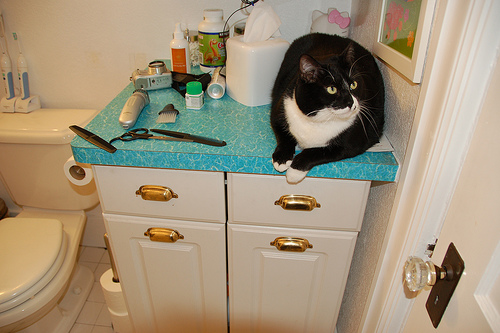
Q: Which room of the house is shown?
A: It is a bathroom.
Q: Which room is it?
A: It is a bathroom.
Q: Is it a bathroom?
A: Yes, it is a bathroom.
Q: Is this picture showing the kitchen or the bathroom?
A: It is showing the bathroom.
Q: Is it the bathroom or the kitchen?
A: It is the bathroom.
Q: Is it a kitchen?
A: No, it is a bathroom.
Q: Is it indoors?
A: Yes, it is indoors.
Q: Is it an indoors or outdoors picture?
A: It is indoors.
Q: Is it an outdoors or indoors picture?
A: It is indoors.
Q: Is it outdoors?
A: No, it is indoors.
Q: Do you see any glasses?
A: No, there are no glasses.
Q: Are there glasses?
A: No, there are no glasses.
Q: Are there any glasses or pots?
A: No, there are no glasses or pots.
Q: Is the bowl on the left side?
A: Yes, the bowl is on the left of the image.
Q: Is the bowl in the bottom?
A: Yes, the bowl is in the bottom of the image.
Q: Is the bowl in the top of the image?
A: No, the bowl is in the bottom of the image.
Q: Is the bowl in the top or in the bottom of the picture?
A: The bowl is in the bottom of the image.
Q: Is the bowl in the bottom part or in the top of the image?
A: The bowl is in the bottom of the image.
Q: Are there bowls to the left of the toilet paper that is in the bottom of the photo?
A: Yes, there is a bowl to the left of the toilet paper.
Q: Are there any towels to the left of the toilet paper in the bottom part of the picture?
A: No, there is a bowl to the left of the toilet paper.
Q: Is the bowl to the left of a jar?
A: No, the bowl is to the left of a toilet paper.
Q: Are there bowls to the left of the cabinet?
A: Yes, there is a bowl to the left of the cabinet.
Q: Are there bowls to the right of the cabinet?
A: No, the bowl is to the left of the cabinet.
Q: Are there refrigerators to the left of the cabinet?
A: No, there is a bowl to the left of the cabinet.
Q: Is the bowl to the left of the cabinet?
A: Yes, the bowl is to the left of the cabinet.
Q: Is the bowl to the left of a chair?
A: No, the bowl is to the left of the cabinet.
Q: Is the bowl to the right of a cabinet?
A: No, the bowl is to the left of a cabinet.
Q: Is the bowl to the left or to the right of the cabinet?
A: The bowl is to the left of the cabinet.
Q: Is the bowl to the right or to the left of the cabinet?
A: The bowl is to the left of the cabinet.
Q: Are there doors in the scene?
A: Yes, there is a door.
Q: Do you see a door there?
A: Yes, there is a door.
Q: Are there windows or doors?
A: Yes, there is a door.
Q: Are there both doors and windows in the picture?
A: No, there is a door but no windows.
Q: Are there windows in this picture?
A: No, there are no windows.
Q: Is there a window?
A: No, there are no windows.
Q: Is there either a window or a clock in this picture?
A: No, there are no windows or clocks.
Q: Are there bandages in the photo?
A: No, there are no bandages.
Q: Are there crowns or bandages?
A: No, there are no bandages or crowns.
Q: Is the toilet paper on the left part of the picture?
A: Yes, the toilet paper is on the left of the image.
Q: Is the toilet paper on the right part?
A: No, the toilet paper is on the left of the image.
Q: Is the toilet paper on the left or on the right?
A: The toilet paper is on the left of the image.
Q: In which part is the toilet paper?
A: The toilet paper is on the left of the image.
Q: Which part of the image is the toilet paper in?
A: The toilet paper is on the left of the image.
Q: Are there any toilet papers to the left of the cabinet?
A: Yes, there is a toilet paper to the left of the cabinet.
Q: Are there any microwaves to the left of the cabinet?
A: No, there is a toilet paper to the left of the cabinet.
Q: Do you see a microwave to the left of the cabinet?
A: No, there is a toilet paper to the left of the cabinet.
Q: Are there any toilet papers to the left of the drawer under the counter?
A: Yes, there is a toilet paper to the left of the drawer.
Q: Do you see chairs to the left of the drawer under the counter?
A: No, there is a toilet paper to the left of the drawer.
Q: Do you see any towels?
A: No, there are no towels.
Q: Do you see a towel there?
A: No, there are no towels.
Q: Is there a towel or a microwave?
A: No, there are no towels or microwaves.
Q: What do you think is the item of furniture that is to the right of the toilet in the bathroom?
A: The piece of furniture is a drawer.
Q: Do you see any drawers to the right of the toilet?
A: Yes, there is a drawer to the right of the toilet.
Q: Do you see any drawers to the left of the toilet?
A: No, the drawer is to the right of the toilet.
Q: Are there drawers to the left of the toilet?
A: No, the drawer is to the right of the toilet.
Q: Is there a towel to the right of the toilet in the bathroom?
A: No, there is a drawer to the right of the toilet.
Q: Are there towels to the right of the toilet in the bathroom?
A: No, there is a drawer to the right of the toilet.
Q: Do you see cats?
A: Yes, there is a cat.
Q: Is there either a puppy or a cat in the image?
A: Yes, there is a cat.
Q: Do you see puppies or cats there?
A: Yes, there is a cat.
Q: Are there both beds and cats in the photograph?
A: No, there is a cat but no beds.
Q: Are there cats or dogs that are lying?
A: Yes, the cat is lying.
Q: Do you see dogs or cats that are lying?
A: Yes, the cat is lying.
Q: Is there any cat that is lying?
A: Yes, there is a cat that is lying.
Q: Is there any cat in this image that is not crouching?
A: Yes, there is a cat that is lying.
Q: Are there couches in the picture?
A: No, there are no couches.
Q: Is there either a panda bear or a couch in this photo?
A: No, there are no couches or pandas.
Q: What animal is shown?
A: The animal is a cat.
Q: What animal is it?
A: The animal is a cat.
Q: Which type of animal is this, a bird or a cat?
A: That is a cat.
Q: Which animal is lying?
A: The animal is a cat.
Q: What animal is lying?
A: The animal is a cat.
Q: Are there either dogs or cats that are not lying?
A: No, there is a cat but it is lying.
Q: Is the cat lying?
A: Yes, the cat is lying.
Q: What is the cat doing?
A: The cat is lying.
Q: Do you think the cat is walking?
A: No, the cat is lying.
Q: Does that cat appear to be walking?
A: No, the cat is lying.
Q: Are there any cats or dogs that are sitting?
A: No, there is a cat but it is lying.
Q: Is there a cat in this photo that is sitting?
A: No, there is a cat but it is lying.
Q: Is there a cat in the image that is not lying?
A: No, there is a cat but it is lying.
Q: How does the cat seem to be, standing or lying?
A: The cat is lying.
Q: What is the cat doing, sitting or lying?
A: The cat is lying.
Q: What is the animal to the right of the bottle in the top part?
A: The animal is a cat.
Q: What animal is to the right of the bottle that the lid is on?
A: The animal is a cat.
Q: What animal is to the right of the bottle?
A: The animal is a cat.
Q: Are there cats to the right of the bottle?
A: Yes, there is a cat to the right of the bottle.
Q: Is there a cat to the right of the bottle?
A: Yes, there is a cat to the right of the bottle.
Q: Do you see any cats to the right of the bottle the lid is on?
A: Yes, there is a cat to the right of the bottle.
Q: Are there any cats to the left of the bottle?
A: No, the cat is to the right of the bottle.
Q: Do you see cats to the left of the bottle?
A: No, the cat is to the right of the bottle.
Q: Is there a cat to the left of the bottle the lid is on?
A: No, the cat is to the right of the bottle.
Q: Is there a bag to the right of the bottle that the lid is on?
A: No, there is a cat to the right of the bottle.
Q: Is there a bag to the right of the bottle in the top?
A: No, there is a cat to the right of the bottle.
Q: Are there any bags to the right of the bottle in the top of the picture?
A: No, there is a cat to the right of the bottle.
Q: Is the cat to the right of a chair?
A: No, the cat is to the right of a bottle.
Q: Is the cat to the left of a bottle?
A: No, the cat is to the right of a bottle.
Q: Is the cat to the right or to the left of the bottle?
A: The cat is to the right of the bottle.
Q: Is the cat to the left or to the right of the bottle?
A: The cat is to the right of the bottle.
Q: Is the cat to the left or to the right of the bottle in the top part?
A: The cat is to the right of the bottle.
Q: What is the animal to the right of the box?
A: The animal is a cat.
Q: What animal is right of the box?
A: The animal is a cat.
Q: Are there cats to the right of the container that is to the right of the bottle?
A: Yes, there is a cat to the right of the box.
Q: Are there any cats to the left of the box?
A: No, the cat is to the right of the box.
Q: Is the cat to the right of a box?
A: Yes, the cat is to the right of a box.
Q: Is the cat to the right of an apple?
A: No, the cat is to the right of a box.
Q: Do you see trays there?
A: No, there are no trays.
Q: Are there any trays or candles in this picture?
A: No, there are no trays or candles.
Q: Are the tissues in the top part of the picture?
A: Yes, the tissues are in the top of the image.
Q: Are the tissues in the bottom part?
A: No, the tissues are in the top of the image.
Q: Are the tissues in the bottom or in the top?
A: The tissues are in the top of the image.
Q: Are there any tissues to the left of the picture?
A: Yes, there are tissues to the left of the picture.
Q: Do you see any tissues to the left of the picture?
A: Yes, there are tissues to the left of the picture.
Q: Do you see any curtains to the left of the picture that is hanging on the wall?
A: No, there are tissues to the left of the picture.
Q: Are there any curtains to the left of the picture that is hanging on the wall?
A: No, there are tissues to the left of the picture.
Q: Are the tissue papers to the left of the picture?
A: Yes, the tissue papers are to the left of the picture.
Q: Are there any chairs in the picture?
A: No, there are no chairs.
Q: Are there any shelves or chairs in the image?
A: No, there are no chairs or shelves.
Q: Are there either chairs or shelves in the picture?
A: No, there are no chairs or shelves.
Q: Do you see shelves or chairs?
A: No, there are no chairs or shelves.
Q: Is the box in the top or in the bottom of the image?
A: The box is in the top of the image.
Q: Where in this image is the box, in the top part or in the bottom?
A: The box is in the top of the image.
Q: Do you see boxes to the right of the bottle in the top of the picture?
A: Yes, there is a box to the right of the bottle.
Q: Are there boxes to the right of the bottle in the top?
A: Yes, there is a box to the right of the bottle.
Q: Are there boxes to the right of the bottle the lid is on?
A: Yes, there is a box to the right of the bottle.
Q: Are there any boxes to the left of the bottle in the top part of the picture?
A: No, the box is to the right of the bottle.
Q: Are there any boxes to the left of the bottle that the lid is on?
A: No, the box is to the right of the bottle.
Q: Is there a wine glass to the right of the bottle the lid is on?
A: No, there is a box to the right of the bottle.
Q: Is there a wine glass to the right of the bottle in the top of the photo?
A: No, there is a box to the right of the bottle.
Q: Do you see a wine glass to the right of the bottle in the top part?
A: No, there is a box to the right of the bottle.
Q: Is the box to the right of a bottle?
A: Yes, the box is to the right of a bottle.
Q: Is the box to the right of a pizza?
A: No, the box is to the right of a bottle.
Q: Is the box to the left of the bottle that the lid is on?
A: No, the box is to the right of the bottle.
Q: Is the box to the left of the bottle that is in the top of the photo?
A: No, the box is to the right of the bottle.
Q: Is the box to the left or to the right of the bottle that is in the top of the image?
A: The box is to the right of the bottle.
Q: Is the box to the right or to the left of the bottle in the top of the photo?
A: The box is to the right of the bottle.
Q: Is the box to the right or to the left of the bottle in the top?
A: The box is to the right of the bottle.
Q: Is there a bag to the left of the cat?
A: No, there is a box to the left of the cat.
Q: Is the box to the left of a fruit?
A: No, the box is to the left of the cat.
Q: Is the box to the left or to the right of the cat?
A: The box is to the left of the cat.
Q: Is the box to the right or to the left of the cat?
A: The box is to the left of the cat.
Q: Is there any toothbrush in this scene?
A: Yes, there is a toothbrush.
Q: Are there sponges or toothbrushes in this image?
A: Yes, there is a toothbrush.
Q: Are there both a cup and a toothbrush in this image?
A: No, there is a toothbrush but no cups.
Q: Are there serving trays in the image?
A: No, there are no serving trays.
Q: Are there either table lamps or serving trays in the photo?
A: No, there are no serving trays or table lamps.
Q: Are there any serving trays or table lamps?
A: No, there are no serving trays or table lamps.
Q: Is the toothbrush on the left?
A: Yes, the toothbrush is on the left of the image.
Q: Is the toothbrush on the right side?
A: No, the toothbrush is on the left of the image.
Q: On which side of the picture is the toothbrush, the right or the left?
A: The toothbrush is on the left of the image.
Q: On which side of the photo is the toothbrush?
A: The toothbrush is on the left of the image.